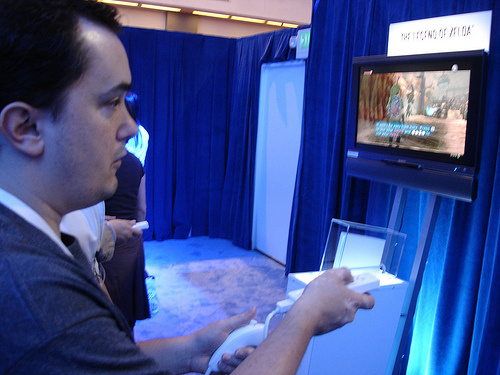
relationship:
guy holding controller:
[0, 0, 382, 373] [267, 262, 387, 325]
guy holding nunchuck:
[0, 0, 382, 373] [206, 316, 264, 366]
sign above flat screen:
[374, 5, 496, 62] [327, 38, 499, 206]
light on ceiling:
[282, 22, 297, 29] [96, 0, 311, 37]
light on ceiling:
[265, 20, 280, 25] [96, 0, 311, 37]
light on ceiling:
[230, 13, 265, 25] [96, 0, 311, 37]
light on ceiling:
[192, 10, 228, 17] [96, 0, 311, 37]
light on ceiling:
[140, 3, 182, 12] [96, 0, 311, 37]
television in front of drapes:
[320, 38, 496, 213] [450, 200, 487, 293]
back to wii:
[112, 123, 147, 220] [325, 228, 393, 288]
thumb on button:
[315, 260, 355, 290] [349, 266, 372, 282]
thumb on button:
[222, 294, 259, 330] [245, 313, 263, 329]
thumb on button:
[115, 212, 142, 227] [245, 313, 263, 329]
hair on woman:
[122, 91, 143, 150] [127, 89, 156, 331]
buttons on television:
[373, 152, 483, 190] [338, 48, 486, 168]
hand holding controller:
[292, 267, 374, 338] [267, 262, 387, 325]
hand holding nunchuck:
[185, 309, 256, 371] [204, 316, 267, 373]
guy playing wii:
[0, 0, 382, 373] [330, 255, 395, 321]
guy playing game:
[0, 0, 385, 373] [271, 189, 409, 321]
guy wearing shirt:
[0, 0, 385, 373] [4, 191, 243, 371]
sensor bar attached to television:
[343, 148, 482, 179] [344, 48, 491, 203]